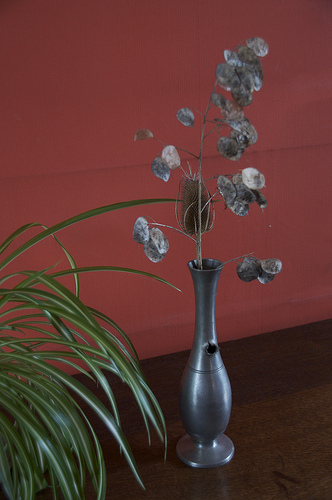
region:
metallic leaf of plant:
[260, 257, 278, 272]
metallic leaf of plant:
[157, 141, 178, 169]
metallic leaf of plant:
[152, 232, 176, 254]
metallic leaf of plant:
[171, 108, 191, 131]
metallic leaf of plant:
[239, 38, 272, 58]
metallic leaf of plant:
[230, 83, 253, 111]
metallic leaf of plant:
[212, 64, 238, 91]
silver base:
[133, 231, 251, 479]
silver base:
[163, 287, 238, 462]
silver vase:
[185, 239, 261, 492]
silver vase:
[129, 221, 240, 491]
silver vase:
[164, 301, 238, 463]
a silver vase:
[179, 255, 234, 470]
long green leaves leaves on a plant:
[0, 190, 184, 498]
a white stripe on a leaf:
[66, 382, 121, 438]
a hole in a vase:
[203, 340, 220, 359]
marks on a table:
[269, 467, 306, 495]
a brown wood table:
[0, 320, 328, 499]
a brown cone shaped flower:
[173, 162, 216, 235]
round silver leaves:
[131, 216, 176, 261]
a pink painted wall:
[0, 1, 330, 378]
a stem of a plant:
[194, 83, 219, 266]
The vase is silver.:
[189, 267, 239, 453]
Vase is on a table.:
[249, 405, 306, 478]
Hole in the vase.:
[198, 335, 223, 362]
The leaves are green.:
[1, 293, 89, 482]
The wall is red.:
[106, 275, 173, 335]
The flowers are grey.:
[214, 57, 257, 155]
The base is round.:
[172, 428, 240, 470]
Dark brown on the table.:
[267, 458, 300, 498]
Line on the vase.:
[180, 356, 226, 378]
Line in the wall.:
[71, 136, 330, 177]